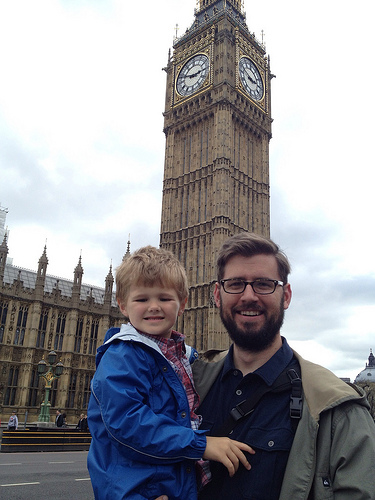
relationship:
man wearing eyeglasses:
[181, 233, 370, 498] [216, 276, 287, 293]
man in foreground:
[181, 233, 370, 498] [65, 272, 349, 488]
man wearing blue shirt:
[181, 233, 370, 498] [198, 372, 286, 485]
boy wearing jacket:
[93, 244, 208, 480] [79, 324, 229, 492]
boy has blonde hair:
[93, 244, 208, 480] [109, 245, 189, 303]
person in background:
[76, 412, 91, 427] [5, 378, 90, 446]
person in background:
[52, 405, 67, 425] [5, 378, 90, 446]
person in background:
[6, 411, 18, 428] [5, 378, 90, 446]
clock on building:
[171, 54, 216, 95] [163, 7, 270, 252]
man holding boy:
[181, 233, 370, 498] [107, 238, 233, 495]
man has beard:
[181, 233, 370, 498] [214, 286, 285, 355]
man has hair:
[181, 233, 370, 498] [215, 235, 287, 261]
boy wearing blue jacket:
[93, 244, 208, 480] [95, 322, 205, 498]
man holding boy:
[181, 233, 370, 498] [93, 244, 208, 480]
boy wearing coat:
[93, 244, 208, 480] [85, 320, 215, 498]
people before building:
[2, 408, 90, 436] [151, 99, 262, 241]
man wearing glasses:
[181, 233, 370, 498] [227, 269, 288, 301]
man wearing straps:
[181, 233, 370, 498] [221, 361, 303, 440]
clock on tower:
[171, 54, 216, 95] [159, 3, 275, 247]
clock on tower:
[237, 54, 270, 104] [159, 3, 275, 247]